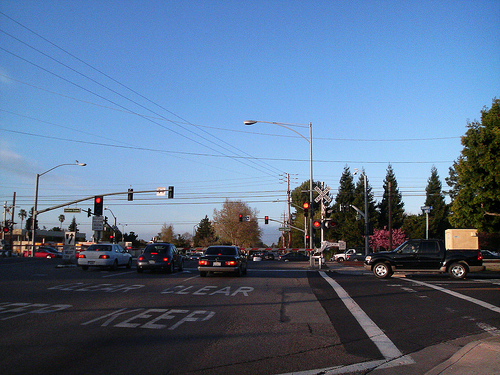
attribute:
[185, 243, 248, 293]
car — waiting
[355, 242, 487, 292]
truck — sitting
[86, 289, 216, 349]
word — keep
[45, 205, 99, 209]
sign — green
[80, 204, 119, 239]
tree — leafy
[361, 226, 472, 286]
truck — black, hauling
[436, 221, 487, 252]
box — large, wooden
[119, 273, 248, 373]
notice — painted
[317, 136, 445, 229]
trees — pine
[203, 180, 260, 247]
leaves — autumn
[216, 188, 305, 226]
lights — suspended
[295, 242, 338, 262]
gate — crossing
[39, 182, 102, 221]
sign — suspended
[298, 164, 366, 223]
sign — crossing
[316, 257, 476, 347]
crosswalk — empty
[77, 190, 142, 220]
light — red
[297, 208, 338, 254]
light — red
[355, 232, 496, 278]
truck — black, pickup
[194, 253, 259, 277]
brake lights — red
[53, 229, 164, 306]
car — white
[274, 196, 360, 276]
signal — crossing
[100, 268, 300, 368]
writing — white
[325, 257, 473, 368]
lines — white, painted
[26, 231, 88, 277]
car — red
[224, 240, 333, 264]
crossing rail — red , white 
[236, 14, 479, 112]
sky — blue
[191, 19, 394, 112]
sky — clear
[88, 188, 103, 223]
traffic light — red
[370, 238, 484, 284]
black truck — black 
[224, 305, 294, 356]
asphalt — black 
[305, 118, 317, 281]
support pole — Vertical 